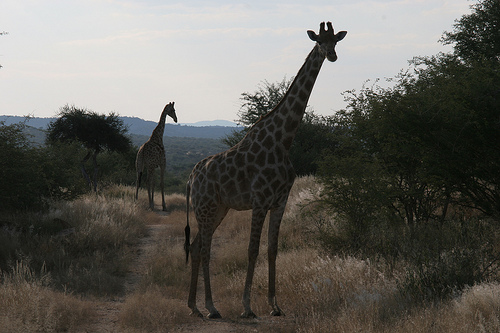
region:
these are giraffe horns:
[315, 22, 344, 32]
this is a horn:
[317, 21, 327, 31]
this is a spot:
[257, 128, 278, 154]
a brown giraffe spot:
[251, 146, 271, 169]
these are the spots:
[227, 145, 295, 190]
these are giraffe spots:
[227, 153, 266, 179]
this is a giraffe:
[106, 86, 192, 213]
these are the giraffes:
[106, 21, 376, 326]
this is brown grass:
[321, 262, 387, 317]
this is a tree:
[45, 98, 148, 192]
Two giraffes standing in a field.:
[26, 18, 401, 320]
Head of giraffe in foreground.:
[303, 10, 352, 72]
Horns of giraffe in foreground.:
[308, 12, 338, 31]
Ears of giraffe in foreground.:
[307, 24, 347, 51]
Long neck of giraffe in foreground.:
[253, 43, 324, 138]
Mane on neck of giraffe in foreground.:
[249, 55, 314, 125]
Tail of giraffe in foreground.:
[177, 170, 192, 269]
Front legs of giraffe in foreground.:
[233, 195, 292, 322]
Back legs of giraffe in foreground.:
[186, 209, 228, 324]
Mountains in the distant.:
[18, 105, 340, 145]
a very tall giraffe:
[181, 18, 347, 322]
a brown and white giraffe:
[183, 19, 347, 324]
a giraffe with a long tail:
[177, 169, 199, 267]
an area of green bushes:
[225, 24, 498, 251]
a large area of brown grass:
[0, 173, 499, 331]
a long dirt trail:
[92, 193, 174, 331]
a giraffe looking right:
[131, 101, 179, 216]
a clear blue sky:
[1, 0, 498, 125]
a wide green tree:
[45, 104, 135, 174]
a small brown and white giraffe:
[132, 101, 178, 213]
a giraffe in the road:
[177, 18, 347, 317]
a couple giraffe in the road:
[127, 17, 347, 328]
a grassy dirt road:
[69, 216, 167, 332]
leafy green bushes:
[360, 25, 496, 296]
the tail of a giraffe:
[177, 180, 187, 265]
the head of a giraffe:
[305, 16, 345, 61]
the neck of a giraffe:
[277, 65, 317, 135]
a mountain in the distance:
[190, 116, 235, 126]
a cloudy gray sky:
[15, 10, 260, 90]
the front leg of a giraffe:
[239, 204, 267, 325]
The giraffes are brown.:
[118, 20, 346, 325]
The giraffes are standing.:
[110, 16, 324, 330]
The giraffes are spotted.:
[112, 15, 358, 315]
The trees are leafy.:
[340, 62, 492, 302]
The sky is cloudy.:
[12, 6, 424, 117]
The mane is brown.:
[238, 39, 314, 124]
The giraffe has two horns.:
[315, 19, 338, 34]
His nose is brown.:
[324, 48, 341, 69]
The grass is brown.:
[61, 195, 482, 331]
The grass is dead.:
[6, 185, 493, 327]